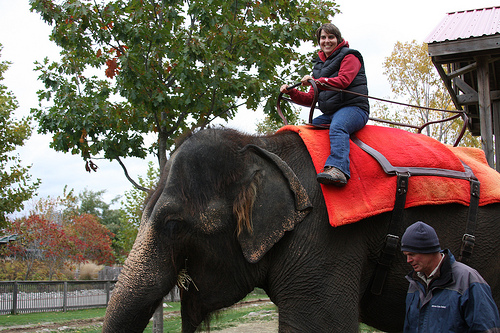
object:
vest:
[312, 47, 369, 111]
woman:
[278, 22, 368, 186]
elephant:
[105, 129, 499, 332]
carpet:
[277, 123, 499, 227]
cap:
[400, 222, 443, 254]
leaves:
[6, 197, 19, 207]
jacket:
[400, 250, 499, 332]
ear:
[235, 146, 314, 264]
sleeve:
[315, 54, 360, 90]